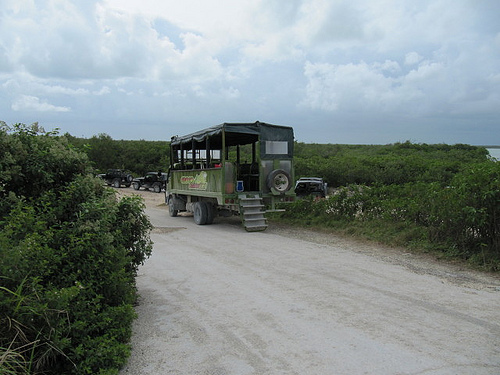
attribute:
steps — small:
[237, 197, 269, 236]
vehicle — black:
[133, 168, 168, 191]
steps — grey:
[238, 190, 265, 230]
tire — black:
[192, 202, 215, 222]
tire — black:
[166, 192, 181, 216]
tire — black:
[269, 167, 292, 196]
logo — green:
[178, 168, 208, 190]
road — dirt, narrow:
[119, 186, 499, 371]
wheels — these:
[160, 193, 224, 226]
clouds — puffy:
[296, 57, 494, 119]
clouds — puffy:
[2, 0, 229, 112]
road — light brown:
[179, 235, 433, 372]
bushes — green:
[3, 122, 148, 369]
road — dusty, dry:
[158, 235, 326, 366]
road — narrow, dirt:
[146, 220, 483, 371]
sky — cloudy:
[8, 6, 496, 123]